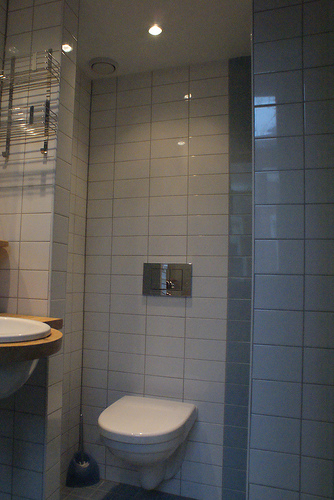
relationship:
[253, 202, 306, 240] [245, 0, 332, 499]
tile on wall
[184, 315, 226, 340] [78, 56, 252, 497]
tile on wall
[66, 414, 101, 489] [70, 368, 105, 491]
brush in corner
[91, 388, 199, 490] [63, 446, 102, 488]
toilet in holder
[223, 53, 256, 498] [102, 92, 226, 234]
tile on wall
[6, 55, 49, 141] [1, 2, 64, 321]
metal on wall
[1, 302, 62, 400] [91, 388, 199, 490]
sink next to toilet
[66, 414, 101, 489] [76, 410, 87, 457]
brush with a blue handle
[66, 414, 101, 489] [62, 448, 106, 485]
brush and a holder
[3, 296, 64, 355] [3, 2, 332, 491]
counter in bathroom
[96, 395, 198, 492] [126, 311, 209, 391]
toilet attached to wall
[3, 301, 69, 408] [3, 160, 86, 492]
sink in wall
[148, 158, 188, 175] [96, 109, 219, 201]
tile in wall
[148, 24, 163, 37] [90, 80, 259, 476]
light in wall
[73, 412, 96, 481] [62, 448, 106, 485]
brush in holder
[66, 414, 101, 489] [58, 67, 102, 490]
brush in corner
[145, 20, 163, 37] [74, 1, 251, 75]
light attached to ceiling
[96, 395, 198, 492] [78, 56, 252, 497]
toilet on wall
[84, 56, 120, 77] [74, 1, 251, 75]
detector on ceiling